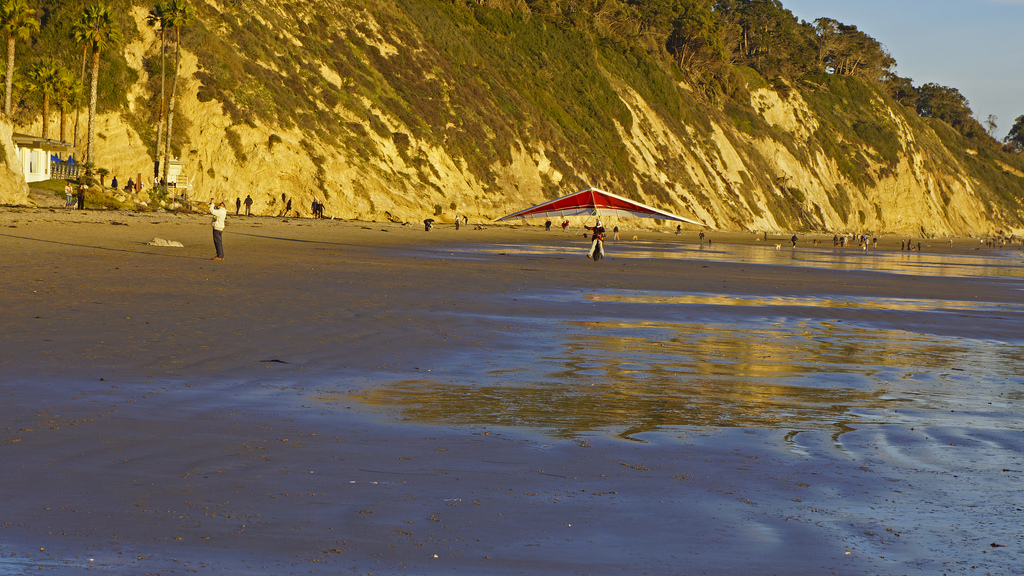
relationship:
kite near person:
[524, 173, 674, 226] [563, 212, 628, 273]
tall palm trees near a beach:
[141, 107, 191, 200] [45, 220, 298, 331]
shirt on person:
[208, 204, 227, 232] [195, 192, 237, 259]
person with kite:
[581, 216, 608, 263] [512, 177, 672, 229]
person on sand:
[205, 197, 232, 262] [80, 217, 402, 263]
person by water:
[581, 216, 608, 263] [325, 252, 946, 551]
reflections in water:
[607, 300, 858, 417] [221, 287, 945, 521]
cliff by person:
[188, 30, 955, 214] [581, 216, 608, 263]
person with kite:
[581, 216, 608, 263] [502, 190, 645, 236]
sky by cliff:
[871, 0, 993, 98] [0, 0, 1022, 230]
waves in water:
[711, 425, 992, 465] [283, 315, 975, 523]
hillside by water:
[199, 32, 992, 210] [204, 274, 976, 549]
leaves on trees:
[750, 17, 884, 74] [830, 23, 971, 132]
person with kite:
[581, 216, 608, 263] [495, 187, 716, 236]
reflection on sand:
[532, 243, 993, 278] [566, 226, 949, 257]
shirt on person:
[204, 190, 231, 234] [191, 179, 243, 272]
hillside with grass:
[0, 0, 1024, 240] [374, 43, 617, 150]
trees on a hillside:
[428, 103, 1020, 104] [261, 203, 719, 258]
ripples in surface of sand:
[542, 380, 1022, 441] [437, 367, 1021, 576]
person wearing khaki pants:
[579, 181, 636, 333] [583, 233, 601, 264]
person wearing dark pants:
[194, 205, 234, 294] [195, 226, 234, 272]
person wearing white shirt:
[205, 197, 232, 262] [216, 213, 234, 233]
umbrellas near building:
[86, 103, 186, 246] [24, 207, 124, 244]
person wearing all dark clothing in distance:
[773, 211, 808, 281] [389, 241, 1012, 468]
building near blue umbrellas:
[9, 131, 83, 183] [101, 205, 173, 229]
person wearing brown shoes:
[166, 157, 273, 276] [210, 248, 236, 261]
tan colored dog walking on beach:
[769, 237, 782, 261] [385, 218, 1016, 292]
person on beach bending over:
[391, 179, 454, 257] [406, 203, 463, 290]